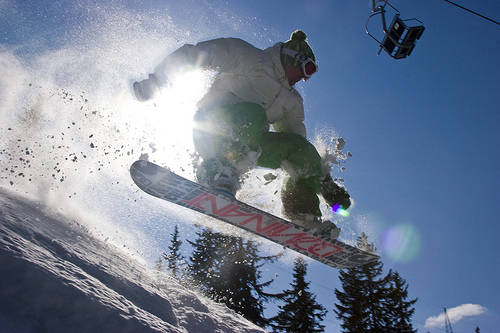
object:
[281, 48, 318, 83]
goggles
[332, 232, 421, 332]
tree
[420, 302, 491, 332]
cloud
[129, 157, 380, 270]
snowboard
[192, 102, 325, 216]
pants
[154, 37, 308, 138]
jacket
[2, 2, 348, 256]
snow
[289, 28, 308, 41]
pom pom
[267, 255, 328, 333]
trees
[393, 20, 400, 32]
sticker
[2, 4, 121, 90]
air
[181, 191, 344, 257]
design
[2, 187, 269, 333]
snow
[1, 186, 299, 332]
ground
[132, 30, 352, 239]
man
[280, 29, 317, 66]
beanie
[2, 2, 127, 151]
sky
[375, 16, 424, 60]
bench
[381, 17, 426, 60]
chair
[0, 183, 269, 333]
hill